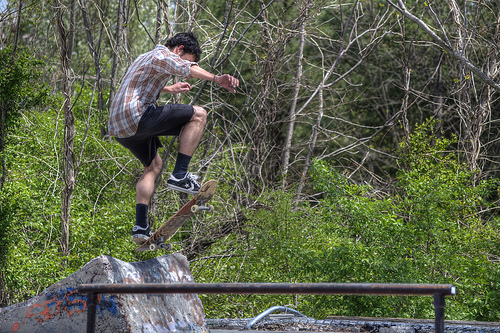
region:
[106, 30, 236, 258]
Man is doing skateboard tricl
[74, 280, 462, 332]
Long rusty brown metal rail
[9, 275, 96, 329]
Orange graffiti on gray rock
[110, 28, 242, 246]
Man wearing plaid shirt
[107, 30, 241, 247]
Man wearing black shorts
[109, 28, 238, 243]
Man wearing black sock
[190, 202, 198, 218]
Beige wheel on skateboard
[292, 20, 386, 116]
Tree branch is long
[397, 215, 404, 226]
Leaf is green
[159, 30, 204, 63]
Hair is black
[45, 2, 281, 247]
Man skateboarding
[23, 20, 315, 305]
Man skateboarding over a rock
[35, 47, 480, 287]
Forest behind the man skateboarding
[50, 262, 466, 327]
Railing beside the rock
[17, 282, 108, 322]
Graffiti painted on the rock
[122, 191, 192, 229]
Designs on the underside of the skateboard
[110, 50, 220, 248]
Man is wearing a plaid shirt, black shorts, black socks and black shoes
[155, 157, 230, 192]
Man is wearing converse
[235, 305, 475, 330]
Springs of a trampoline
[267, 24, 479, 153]
Trees with no leaves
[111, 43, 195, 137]
the man is wearing a plaid shirt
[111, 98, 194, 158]
the man is wearing shorts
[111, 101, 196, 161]
the shorts are black in color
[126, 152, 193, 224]
the man is wearing socks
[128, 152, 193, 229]
the socks are black in color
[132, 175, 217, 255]
the skateboard is pointing up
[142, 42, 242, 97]
the man's arms are extended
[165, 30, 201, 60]
the man has short hair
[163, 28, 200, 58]
the man's hair is black in color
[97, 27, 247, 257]
the skater is in mid air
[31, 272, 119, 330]
graffite on the ramp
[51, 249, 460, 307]
skateboard railing next to ramp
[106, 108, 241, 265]
skateboard is in the air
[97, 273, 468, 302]
skate railing has rust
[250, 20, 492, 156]
branches do not have leaves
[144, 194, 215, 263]
skateboard has white wheels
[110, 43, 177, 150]
skater is wearing a plaid shirt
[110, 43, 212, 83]
skater has his sleeves rolled up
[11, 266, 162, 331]
graffiti is red and blue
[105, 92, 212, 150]
skater has on black shorts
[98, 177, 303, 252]
A skateboard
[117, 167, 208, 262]
Graffiti and designs on underside of skateboard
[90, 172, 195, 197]
Man is wearing black converse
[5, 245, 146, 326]
Graffiti on the rock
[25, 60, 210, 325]
Man is skateboarding over a rock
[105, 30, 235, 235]
Man is wearing a plaid shirt, black shorts and black shoes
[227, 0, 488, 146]
Trees with no leaves on them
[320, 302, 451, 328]
The springs of a trampoline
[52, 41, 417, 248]
A forest behind the man skateboarding